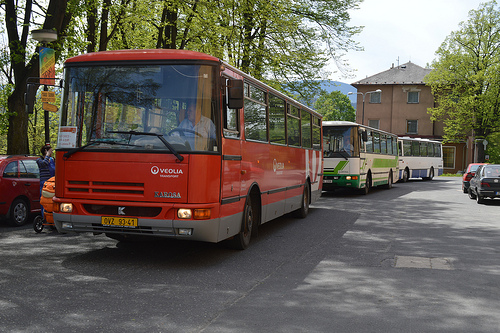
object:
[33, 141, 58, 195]
person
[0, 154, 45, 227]
car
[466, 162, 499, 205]
car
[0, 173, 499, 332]
street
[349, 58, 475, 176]
building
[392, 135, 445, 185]
bus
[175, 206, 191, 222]
lights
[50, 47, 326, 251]
bus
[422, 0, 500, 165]
tree